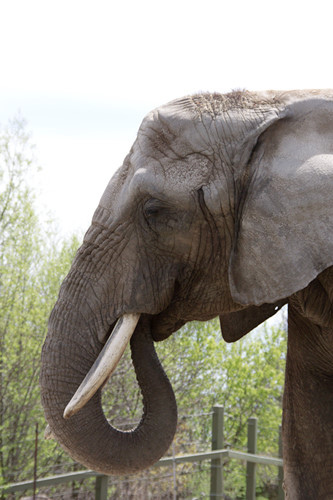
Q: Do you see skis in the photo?
A: No, there are no skis.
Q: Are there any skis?
A: No, there are no skis.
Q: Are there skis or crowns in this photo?
A: No, there are no skis or crowns.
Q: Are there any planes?
A: No, there are no planes.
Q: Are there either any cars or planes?
A: No, there are no planes or cars.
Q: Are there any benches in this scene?
A: No, there are no benches.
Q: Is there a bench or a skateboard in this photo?
A: No, there are no benches or skateboards.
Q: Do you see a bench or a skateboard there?
A: No, there are no benches or skateboards.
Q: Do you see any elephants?
A: Yes, there is an elephant.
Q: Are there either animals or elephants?
A: Yes, there is an elephant.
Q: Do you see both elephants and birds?
A: No, there is an elephant but no birds.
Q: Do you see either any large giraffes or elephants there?
A: Yes, there is a large elephant.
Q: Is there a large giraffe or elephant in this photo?
A: Yes, there is a large elephant.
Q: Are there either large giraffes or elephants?
A: Yes, there is a large elephant.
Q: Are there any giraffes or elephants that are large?
A: Yes, the elephant is large.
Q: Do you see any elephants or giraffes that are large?
A: Yes, the elephant is large.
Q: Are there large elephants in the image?
A: Yes, there is a large elephant.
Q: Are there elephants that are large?
A: Yes, there is an elephant that is large.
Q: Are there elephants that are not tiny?
A: Yes, there is a large elephant.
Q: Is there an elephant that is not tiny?
A: Yes, there is a large elephant.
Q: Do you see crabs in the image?
A: No, there are no crabs.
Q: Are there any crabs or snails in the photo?
A: No, there are no crabs or snails.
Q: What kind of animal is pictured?
A: The animal is an elephant.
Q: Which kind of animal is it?
A: The animal is an elephant.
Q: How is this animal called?
A: That is an elephant.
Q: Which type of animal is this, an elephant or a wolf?
A: That is an elephant.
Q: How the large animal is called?
A: The animal is an elephant.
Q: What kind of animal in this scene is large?
A: The animal is an elephant.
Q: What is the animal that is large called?
A: The animal is an elephant.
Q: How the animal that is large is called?
A: The animal is an elephant.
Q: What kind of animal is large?
A: The animal is an elephant.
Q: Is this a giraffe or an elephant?
A: This is an elephant.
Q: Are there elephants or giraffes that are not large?
A: No, there is an elephant but it is large.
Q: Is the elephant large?
A: Yes, the elephant is large.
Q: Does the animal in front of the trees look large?
A: Yes, the elephant is large.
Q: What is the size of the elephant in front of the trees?
A: The elephant is large.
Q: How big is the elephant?
A: The elephant is large.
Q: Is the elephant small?
A: No, the elephant is large.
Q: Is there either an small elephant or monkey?
A: No, there is an elephant but it is large.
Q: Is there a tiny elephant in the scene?
A: No, there is an elephant but it is large.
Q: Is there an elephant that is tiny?
A: No, there is an elephant but it is large.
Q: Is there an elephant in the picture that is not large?
A: No, there is an elephant but it is large.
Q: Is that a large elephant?
A: Yes, that is a large elephant.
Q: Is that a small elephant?
A: No, that is a large elephant.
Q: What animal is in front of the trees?
A: The elephant is in front of the trees.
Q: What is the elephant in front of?
A: The elephant is in front of the trees.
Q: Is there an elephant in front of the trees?
A: Yes, there is an elephant in front of the trees.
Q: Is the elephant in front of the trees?
A: Yes, the elephant is in front of the trees.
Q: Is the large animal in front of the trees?
A: Yes, the elephant is in front of the trees.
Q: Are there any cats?
A: No, there are no cats.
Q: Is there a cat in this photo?
A: No, there are no cats.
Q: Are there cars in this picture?
A: No, there are no cars.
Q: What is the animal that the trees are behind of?
A: The animal is an elephant.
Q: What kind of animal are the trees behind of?
A: The trees are behind the elephant.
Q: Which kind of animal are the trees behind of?
A: The trees are behind the elephant.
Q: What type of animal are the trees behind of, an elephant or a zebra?
A: The trees are behind an elephant.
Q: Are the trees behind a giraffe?
A: No, the trees are behind the elephant.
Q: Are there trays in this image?
A: No, there are no trays.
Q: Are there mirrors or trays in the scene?
A: No, there are no trays or mirrors.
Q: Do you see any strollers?
A: No, there are no strollers.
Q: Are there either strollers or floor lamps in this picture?
A: No, there are no strollers or floor lamps.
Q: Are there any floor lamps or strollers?
A: No, there are no strollers or floor lamps.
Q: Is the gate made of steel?
A: Yes, the gate is made of steel.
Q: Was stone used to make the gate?
A: No, the gate is made of steel.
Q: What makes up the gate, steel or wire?
A: The gate is made of steel.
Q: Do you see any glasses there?
A: No, there are no glasses.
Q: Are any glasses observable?
A: No, there are no glasses.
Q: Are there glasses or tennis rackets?
A: No, there are no glasses or tennis rackets.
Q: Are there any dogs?
A: No, there are no dogs.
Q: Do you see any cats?
A: No, there are no cats.